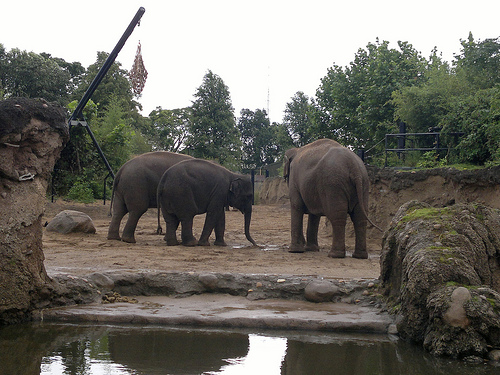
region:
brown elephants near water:
[122, 144, 373, 245]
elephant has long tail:
[294, 138, 399, 256]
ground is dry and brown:
[198, 248, 375, 270]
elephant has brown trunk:
[221, 170, 278, 260]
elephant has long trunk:
[221, 198, 278, 259]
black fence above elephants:
[375, 113, 457, 173]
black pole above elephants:
[54, 4, 142, 121]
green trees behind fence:
[18, 53, 492, 174]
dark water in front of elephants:
[64, 313, 211, 371]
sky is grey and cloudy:
[178, 0, 320, 80]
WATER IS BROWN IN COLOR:
[10, 321, 475, 371]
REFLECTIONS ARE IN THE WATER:
[12, 324, 433, 369]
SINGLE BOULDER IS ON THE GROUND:
[46, 206, 105, 236]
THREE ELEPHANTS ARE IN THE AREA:
[104, 136, 364, 255]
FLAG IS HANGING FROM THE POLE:
[126, 44, 157, 114]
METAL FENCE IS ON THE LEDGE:
[360, 131, 452, 156]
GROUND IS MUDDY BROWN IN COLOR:
[52, 234, 340, 280]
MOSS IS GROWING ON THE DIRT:
[403, 204, 460, 260]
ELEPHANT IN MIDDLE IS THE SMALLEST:
[162, 161, 260, 260]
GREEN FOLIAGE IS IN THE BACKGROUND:
[7, 40, 499, 148]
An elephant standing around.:
[280, 132, 376, 258]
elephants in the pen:
[103, 128, 393, 268]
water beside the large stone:
[17, 317, 414, 374]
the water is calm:
[12, 320, 444, 373]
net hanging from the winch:
[120, 15, 164, 101]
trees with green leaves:
[317, 47, 497, 140]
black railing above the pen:
[352, 124, 492, 170]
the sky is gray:
[156, 28, 308, 84]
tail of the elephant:
[107, 172, 122, 218]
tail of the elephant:
[152, 184, 169, 240]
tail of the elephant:
[339, 166, 384, 230]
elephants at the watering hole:
[105, 137, 379, 266]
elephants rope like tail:
[351, 176, 386, 237]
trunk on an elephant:
[241, 205, 263, 250]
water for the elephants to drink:
[6, 321, 413, 373]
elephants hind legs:
[328, 215, 372, 262]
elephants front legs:
[282, 210, 322, 257]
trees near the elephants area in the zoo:
[155, 28, 498, 126]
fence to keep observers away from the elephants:
[367, 128, 452, 165]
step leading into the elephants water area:
[27, 303, 407, 344]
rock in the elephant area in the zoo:
[44, 206, 99, 237]